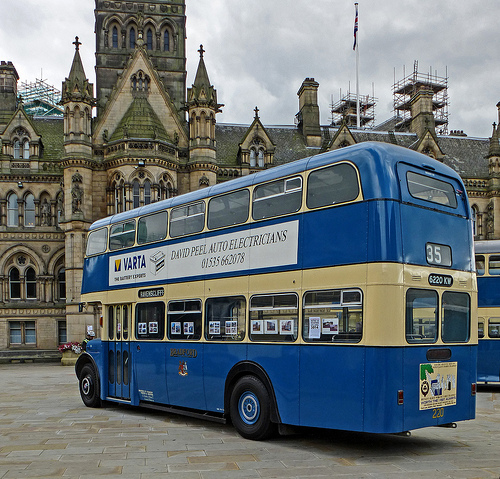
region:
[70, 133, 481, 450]
A parked double decker bus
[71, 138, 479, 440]
A parked double decker bus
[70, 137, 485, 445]
A parked double decker bus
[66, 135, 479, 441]
A parked double decker bus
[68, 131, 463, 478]
blue bus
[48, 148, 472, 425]
bus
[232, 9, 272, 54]
white clouds in blue sky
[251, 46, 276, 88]
white clouds in blue sky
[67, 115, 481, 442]
blue and tan double deck bus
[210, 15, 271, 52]
white clouds in blue sky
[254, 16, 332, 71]
white clouds in blue sky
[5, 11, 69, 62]
white clouds in blue sky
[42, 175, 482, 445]
bus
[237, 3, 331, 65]
white clouds in blue sky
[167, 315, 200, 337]
stickers on the window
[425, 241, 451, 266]
number 35 on the back of the bus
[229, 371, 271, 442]
wheel on the bus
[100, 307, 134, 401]
yellow and blue door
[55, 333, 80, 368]
flowers in front of the building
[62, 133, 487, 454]
blue and yellow double decker bus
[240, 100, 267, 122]
cross on top of the building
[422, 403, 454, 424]
number 220 on the back of the bus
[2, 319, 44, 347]
windows on the building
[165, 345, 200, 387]
logo on the side of the bus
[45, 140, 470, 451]
a blue double decker bus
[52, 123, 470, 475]
a blue double decker bus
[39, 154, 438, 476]
a blue double decker bus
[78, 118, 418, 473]
a blue double decker bus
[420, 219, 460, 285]
the bus number is 35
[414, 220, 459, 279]
the bus number is 35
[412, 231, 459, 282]
the bus number is 35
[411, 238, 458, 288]
the bus number is 35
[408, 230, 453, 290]
the bus number is 35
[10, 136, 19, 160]
a window on a building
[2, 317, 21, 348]
a window on a building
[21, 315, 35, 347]
a window on a building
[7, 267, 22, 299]
a window on a building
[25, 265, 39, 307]
a window on a building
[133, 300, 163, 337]
a window on a bus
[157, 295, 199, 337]
a window on a bus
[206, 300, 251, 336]
a window on a bus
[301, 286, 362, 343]
a window on a bus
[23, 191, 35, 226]
building has a window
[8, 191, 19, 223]
building has a window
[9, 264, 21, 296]
building has a window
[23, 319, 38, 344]
building has a window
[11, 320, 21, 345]
building has a window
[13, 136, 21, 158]
building has a window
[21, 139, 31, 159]
building has a window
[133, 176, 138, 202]
building has a window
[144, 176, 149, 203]
building has a window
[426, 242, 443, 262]
Number 35 printed on the back of the bus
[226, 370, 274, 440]
Tire has blue rim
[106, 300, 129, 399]
Folding door of the bus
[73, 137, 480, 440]
Blue double decker bus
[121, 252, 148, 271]
VARTA printed in blue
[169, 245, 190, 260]
DAVID printed in black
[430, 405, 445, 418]
220 printed in gray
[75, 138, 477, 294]
Upper deck of the bus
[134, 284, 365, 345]
Windows with papers on it